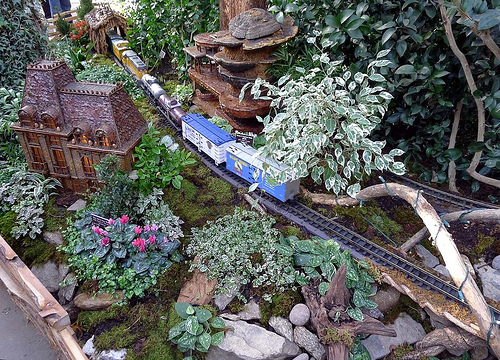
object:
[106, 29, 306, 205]
train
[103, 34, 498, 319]
train tracks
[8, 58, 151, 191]
building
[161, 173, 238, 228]
moss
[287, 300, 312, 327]
rocks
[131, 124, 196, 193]
plants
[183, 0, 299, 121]
wood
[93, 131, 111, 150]
windows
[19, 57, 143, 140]
roof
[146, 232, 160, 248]
flowers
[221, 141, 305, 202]
train car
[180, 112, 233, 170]
train car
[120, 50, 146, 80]
train car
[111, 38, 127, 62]
train car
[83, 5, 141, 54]
tunnel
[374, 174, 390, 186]
lights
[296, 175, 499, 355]
branch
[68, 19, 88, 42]
flowers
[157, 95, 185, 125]
train car